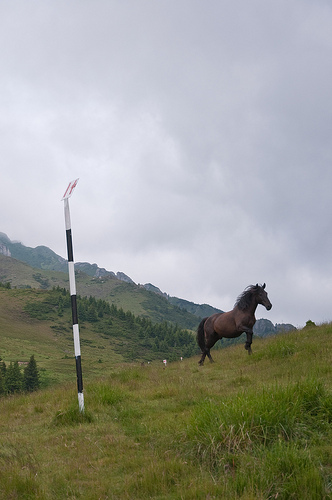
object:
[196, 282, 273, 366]
horse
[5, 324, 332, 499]
grass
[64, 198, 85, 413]
pole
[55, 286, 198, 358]
trees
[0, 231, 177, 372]
hill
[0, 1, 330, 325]
sky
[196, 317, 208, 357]
tail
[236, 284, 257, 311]
mane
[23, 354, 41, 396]
tree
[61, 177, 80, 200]
marker